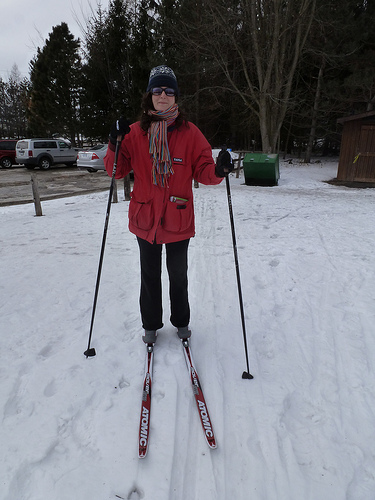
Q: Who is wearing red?
A: Woman skier.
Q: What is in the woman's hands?
A: Poles.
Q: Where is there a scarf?
A: Woman's neck.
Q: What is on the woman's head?
A: Hat.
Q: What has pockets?
A: Jacket.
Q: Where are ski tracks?
A: On the snow.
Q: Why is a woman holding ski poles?
A: To ski.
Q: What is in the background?
A: Trees.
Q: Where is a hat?
A: On woman's head.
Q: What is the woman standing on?
A: Skis.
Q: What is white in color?
A: Snow.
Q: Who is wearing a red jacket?
A: The woman.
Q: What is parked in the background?
A: Vehicles.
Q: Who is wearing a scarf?
A: A woman.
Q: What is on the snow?
A: Foot and ski prints.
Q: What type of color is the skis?
A: Red.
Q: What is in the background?
A: Woods.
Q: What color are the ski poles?
A: Black.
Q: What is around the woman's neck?
A: A scarf.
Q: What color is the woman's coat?
A: Red.